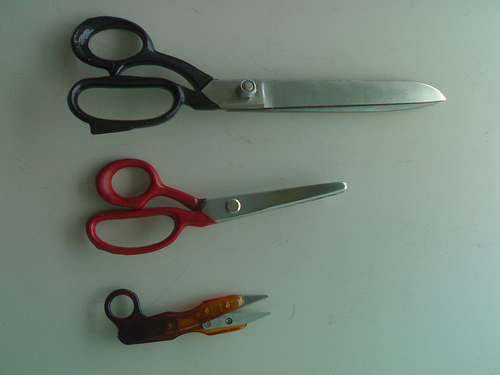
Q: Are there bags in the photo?
A: No, there are no bags.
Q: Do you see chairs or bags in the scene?
A: No, there are no bags or chairs.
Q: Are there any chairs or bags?
A: No, there are no bags or chairs.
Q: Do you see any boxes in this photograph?
A: No, there are no boxes.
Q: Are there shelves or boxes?
A: No, there are no boxes or shelves.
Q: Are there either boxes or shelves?
A: No, there are no boxes or shelves.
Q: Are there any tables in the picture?
A: Yes, there is a table.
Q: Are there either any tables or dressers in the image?
A: Yes, there is a table.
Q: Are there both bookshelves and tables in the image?
A: No, there is a table but no bookshelves.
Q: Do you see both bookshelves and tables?
A: No, there is a table but no bookshelves.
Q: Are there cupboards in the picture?
A: No, there are no cupboards.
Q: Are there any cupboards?
A: No, there are no cupboards.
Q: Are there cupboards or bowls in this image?
A: No, there are no cupboards or bowls.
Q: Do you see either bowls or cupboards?
A: No, there are no cupboards or bowls.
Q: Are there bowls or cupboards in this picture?
A: No, there are no cupboards or bowls.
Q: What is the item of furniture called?
A: The piece of furniture is a table.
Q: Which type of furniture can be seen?
A: The furniture is a table.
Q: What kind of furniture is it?
A: The piece of furniture is a table.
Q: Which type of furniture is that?
A: This is a table.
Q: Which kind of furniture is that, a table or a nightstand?
A: This is a table.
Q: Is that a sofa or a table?
A: That is a table.